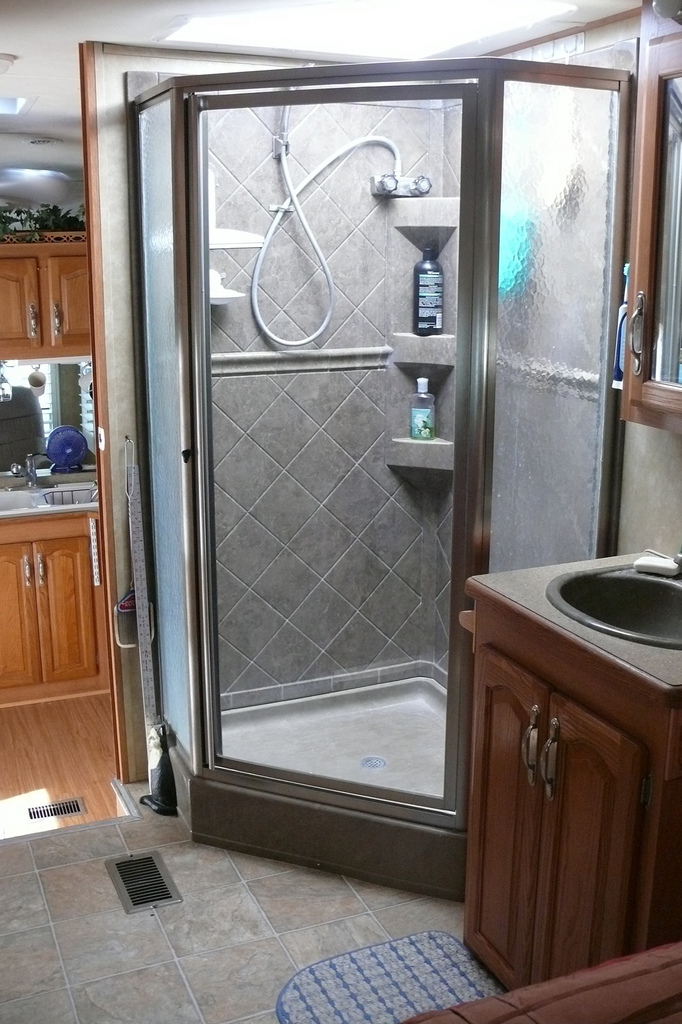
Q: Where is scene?
A: Bathroom.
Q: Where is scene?
A: The bathroom.